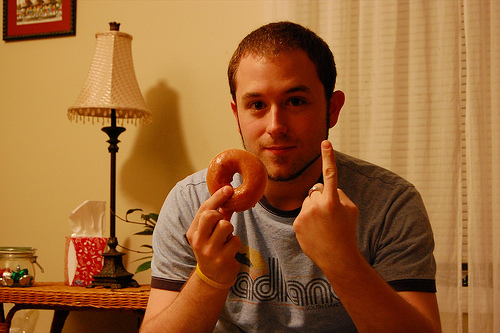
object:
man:
[136, 19, 444, 333]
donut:
[203, 148, 271, 214]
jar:
[0, 245, 45, 290]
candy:
[16, 274, 33, 286]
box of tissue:
[63, 236, 110, 285]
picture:
[3, 0, 78, 43]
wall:
[0, 0, 279, 332]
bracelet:
[190, 263, 238, 292]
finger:
[320, 140, 336, 192]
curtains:
[291, 0, 499, 332]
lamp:
[64, 20, 154, 290]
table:
[0, 281, 152, 314]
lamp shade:
[65, 22, 157, 129]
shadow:
[116, 79, 201, 217]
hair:
[224, 20, 338, 100]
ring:
[306, 185, 323, 196]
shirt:
[146, 148, 438, 332]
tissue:
[67, 197, 106, 238]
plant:
[114, 207, 159, 276]